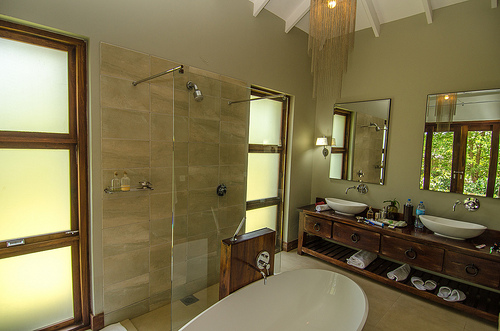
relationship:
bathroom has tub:
[2, 2, 498, 327] [230, 267, 367, 329]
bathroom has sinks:
[2, 2, 498, 327] [323, 196, 487, 238]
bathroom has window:
[2, 2, 498, 327] [245, 88, 294, 227]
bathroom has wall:
[2, 2, 498, 327] [2, 18, 324, 264]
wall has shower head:
[2, 18, 324, 264] [187, 80, 206, 107]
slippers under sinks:
[439, 285, 465, 301] [323, 196, 487, 238]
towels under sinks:
[344, 246, 378, 273] [323, 196, 487, 238]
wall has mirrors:
[2, 18, 324, 264] [334, 88, 498, 186]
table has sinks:
[306, 199, 494, 304] [323, 196, 487, 238]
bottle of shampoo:
[115, 175, 119, 190] [111, 169, 121, 191]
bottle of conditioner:
[122, 175, 132, 190] [121, 170, 132, 192]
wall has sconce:
[2, 18, 324, 264] [320, 149, 328, 156]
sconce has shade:
[320, 149, 328, 156] [316, 134, 326, 148]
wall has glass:
[2, 18, 324, 264] [176, 78, 245, 327]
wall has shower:
[2, 18, 324, 264] [103, 47, 260, 290]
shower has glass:
[103, 47, 260, 290] [176, 78, 245, 327]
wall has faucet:
[2, 18, 324, 264] [347, 184, 357, 194]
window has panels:
[245, 88, 294, 227] [253, 96, 282, 143]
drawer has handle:
[382, 241, 434, 269] [404, 249, 418, 259]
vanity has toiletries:
[306, 199, 494, 304] [365, 183, 427, 230]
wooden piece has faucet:
[221, 228, 278, 288] [255, 246, 269, 283]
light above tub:
[319, 2, 344, 24] [230, 267, 367, 329]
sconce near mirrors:
[320, 149, 328, 156] [334, 88, 498, 186]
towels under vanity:
[344, 246, 378, 273] [323, 196, 487, 238]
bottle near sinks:
[413, 197, 427, 232] [323, 196, 487, 238]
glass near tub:
[176, 78, 245, 327] [230, 267, 367, 329]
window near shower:
[245, 88, 294, 227] [103, 47, 260, 290]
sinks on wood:
[323, 196, 487, 238] [448, 253, 455, 258]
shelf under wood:
[317, 241, 328, 255] [448, 253, 455, 258]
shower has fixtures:
[103, 47, 260, 290] [196, 181, 230, 202]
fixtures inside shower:
[196, 181, 230, 202] [103, 47, 260, 290]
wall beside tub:
[172, 65, 242, 179] [230, 267, 367, 329]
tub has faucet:
[230, 267, 367, 329] [255, 246, 269, 283]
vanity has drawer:
[334, 205, 488, 224] [382, 241, 434, 269]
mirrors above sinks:
[334, 88, 498, 186] [323, 196, 487, 238]